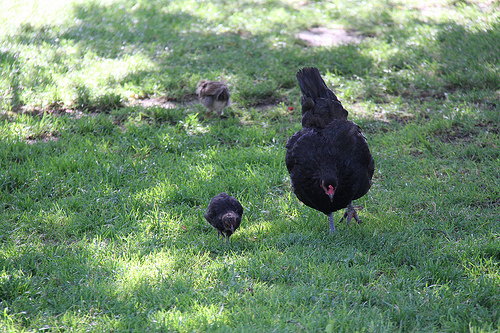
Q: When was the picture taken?
A: Daytime.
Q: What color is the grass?
A: Green.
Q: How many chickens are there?
A: Two.